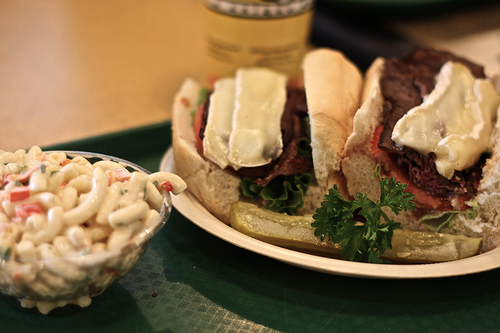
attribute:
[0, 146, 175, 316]
bowl — small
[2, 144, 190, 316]
macaroni salad — creamy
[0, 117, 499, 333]
tray — plastic, green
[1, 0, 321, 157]
table — wooden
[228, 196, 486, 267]
pickle — sliced, covered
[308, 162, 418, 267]
parsley — green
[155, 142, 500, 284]
plate — white, dinner plate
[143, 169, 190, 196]
macaroni — cooked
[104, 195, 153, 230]
macaroni — cooked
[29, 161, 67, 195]
macaroni — cooked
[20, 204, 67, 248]
macaroni — cooked